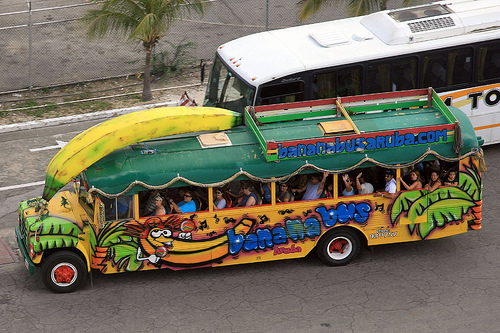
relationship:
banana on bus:
[41, 105, 243, 203] [14, 85, 487, 293]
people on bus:
[141, 159, 460, 217] [14, 85, 487, 293]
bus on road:
[14, 85, 487, 293] [1, 116, 500, 332]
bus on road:
[201, 0, 500, 147] [1, 116, 500, 332]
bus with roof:
[14, 85, 487, 293] [86, 101, 474, 186]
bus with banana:
[14, 85, 487, 293] [41, 105, 243, 203]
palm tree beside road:
[83, 0, 207, 101] [1, 116, 500, 332]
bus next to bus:
[201, 0, 500, 147] [14, 85, 487, 293]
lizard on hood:
[60, 195, 75, 212] [20, 188, 87, 229]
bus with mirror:
[201, 0, 500, 147] [199, 58, 208, 84]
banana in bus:
[132, 216, 258, 265] [14, 85, 487, 293]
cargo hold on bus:
[242, 86, 463, 163] [14, 85, 487, 293]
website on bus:
[277, 127, 449, 159] [14, 85, 487, 293]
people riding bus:
[141, 159, 460, 217] [14, 85, 487, 293]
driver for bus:
[106, 195, 133, 220] [14, 85, 487, 293]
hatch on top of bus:
[195, 129, 232, 148] [14, 85, 487, 293]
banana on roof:
[41, 105, 243, 203] [86, 101, 474, 186]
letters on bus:
[467, 87, 500, 111] [201, 0, 500, 147]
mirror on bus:
[199, 58, 208, 84] [201, 0, 500, 147]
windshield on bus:
[200, 49, 256, 112] [201, 0, 500, 147]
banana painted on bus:
[132, 216, 258, 265] [14, 85, 487, 293]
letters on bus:
[226, 199, 373, 255] [14, 85, 487, 293]